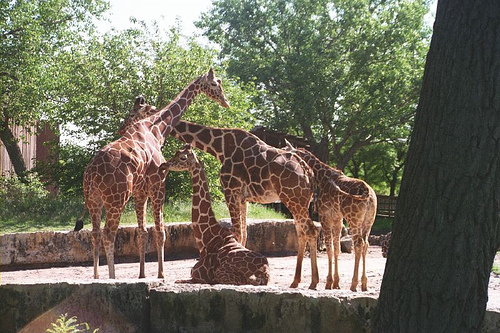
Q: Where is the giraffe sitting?
A: On the ground.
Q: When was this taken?
A: During the day.